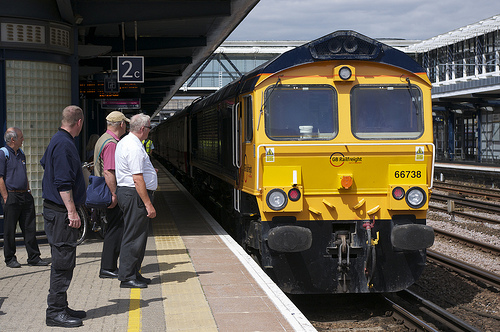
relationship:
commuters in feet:
[40, 105, 87, 328] [45, 308, 82, 327]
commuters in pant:
[40, 105, 87, 328] [37, 204, 83, 306]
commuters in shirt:
[40, 105, 87, 328] [45, 136, 87, 209]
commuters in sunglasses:
[40, 105, 87, 328] [141, 121, 156, 130]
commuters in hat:
[40, 105, 87, 328] [110, 113, 129, 126]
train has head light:
[152, 28, 440, 299] [338, 64, 354, 83]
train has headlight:
[152, 28, 440, 299] [339, 59, 358, 87]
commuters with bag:
[40, 105, 87, 328] [85, 174, 110, 207]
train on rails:
[152, 28, 440, 299] [384, 289, 500, 332]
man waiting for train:
[115, 113, 158, 288] [238, 49, 437, 292]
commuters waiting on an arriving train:
[44, 102, 162, 322] [152, 28, 440, 299]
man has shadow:
[97, 110, 125, 275] [142, 260, 199, 269]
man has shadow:
[117, 106, 153, 288] [146, 270, 216, 285]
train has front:
[148, 29, 435, 294] [276, 86, 419, 256]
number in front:
[394, 165, 423, 179] [276, 86, 419, 256]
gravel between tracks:
[439, 234, 483, 256] [417, 241, 483, 330]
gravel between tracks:
[439, 234, 483, 256] [418, 187, 484, 254]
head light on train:
[338, 66, 352, 80] [152, 28, 440, 299]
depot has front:
[16, 6, 484, 323] [5, 65, 143, 255]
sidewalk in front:
[5, 132, 263, 331] [5, 65, 143, 255]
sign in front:
[116, 56, 145, 83] [36, 44, 158, 206]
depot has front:
[0, 0, 499, 332] [36, 44, 158, 206]